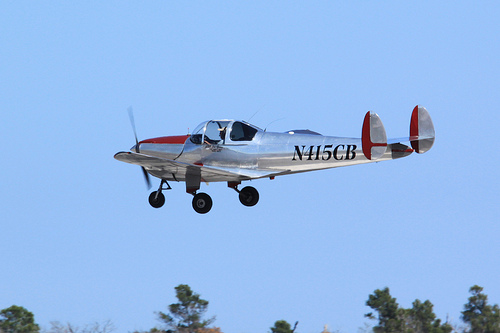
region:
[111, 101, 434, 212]
A silver colored airplane.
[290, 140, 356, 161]
The serial number of an airplane.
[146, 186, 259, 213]
The three tires of an airplane.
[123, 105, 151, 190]
The two helixes of an airplane.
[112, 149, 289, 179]
One of the airplane's wing.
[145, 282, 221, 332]
The head of a beautiful tree.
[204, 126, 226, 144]
The pilot inside the airplane.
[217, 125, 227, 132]
The pilot is wearing a hat.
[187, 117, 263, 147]
The cockpit of a silver airplane.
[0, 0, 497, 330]
The beautiful blue sky above the trees.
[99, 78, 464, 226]
a plane flying in the sky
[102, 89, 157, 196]
a propeller in front of aircraft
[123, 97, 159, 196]
propeller has two blades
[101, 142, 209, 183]
left wing of aircraft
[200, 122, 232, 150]
a pilot inside of aircraft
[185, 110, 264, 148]
windows of an aircraft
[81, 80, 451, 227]
plane is flying on top of trees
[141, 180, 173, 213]
front wheel of plane is black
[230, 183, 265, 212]
back wheel of plane on right side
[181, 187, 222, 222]
back wheel of plane on left side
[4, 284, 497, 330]
tops of green trees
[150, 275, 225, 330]
tree with green leaves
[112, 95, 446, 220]
silver airplane in sky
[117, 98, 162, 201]
spinning airplane propellor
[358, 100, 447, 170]
red paint on airplane tail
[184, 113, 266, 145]
cockpit of airplane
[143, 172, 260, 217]
three small black wheels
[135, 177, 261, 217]
black wheels under airplane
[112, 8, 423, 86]
clear blue cloudless sky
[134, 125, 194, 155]
red paint on silver airplane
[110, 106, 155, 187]
The propeller of the aircraft.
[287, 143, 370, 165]
The aircraft identifier number.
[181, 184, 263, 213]
The rear landing wheels of the aircraft.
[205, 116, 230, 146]
The man who is in control of the plane.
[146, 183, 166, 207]
The front landing gear wheel.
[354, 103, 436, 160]
A pair of tail fins joined with a flat piece of metal.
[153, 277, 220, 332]
The top of the pine tree with the most brown in it.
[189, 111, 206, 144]
The front view glass windshield of the aircraft.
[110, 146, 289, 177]
The left wing of the airplane.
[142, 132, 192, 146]
The area of red on the aircraft between the pilot and the propeller.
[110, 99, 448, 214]
silver and red airplane flying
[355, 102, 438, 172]
tail fins on airplane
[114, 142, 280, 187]
silver wing of airplane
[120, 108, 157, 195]
moving propeller on airplane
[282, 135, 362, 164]
black letters and numbers on airplane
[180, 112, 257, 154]
cockpit of plane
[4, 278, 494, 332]
tops of trees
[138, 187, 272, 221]
three wheels on plane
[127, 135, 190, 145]
red stripe on airplane nose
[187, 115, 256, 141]
windows on airplane